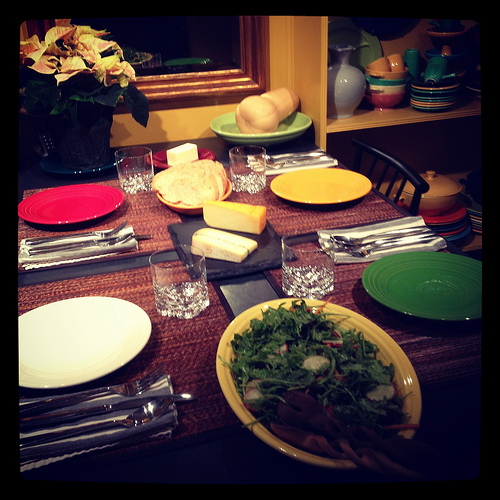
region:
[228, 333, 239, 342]
part of a table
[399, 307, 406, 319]
part of a plate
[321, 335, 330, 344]
part of a vegetable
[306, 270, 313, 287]
part of a glass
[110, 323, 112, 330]
edge of a plate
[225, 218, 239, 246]
part of a cake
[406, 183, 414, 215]
part of a chair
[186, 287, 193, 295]
edge of a glass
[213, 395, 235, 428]
top of a table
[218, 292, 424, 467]
yellow ceramic plate covered with salad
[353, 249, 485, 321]
empty green ceramic plate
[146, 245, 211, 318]
empty fancy drinking glass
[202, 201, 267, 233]
sliced block of muenster cheese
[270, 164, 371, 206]
empty round yellow ceramic plate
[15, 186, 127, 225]
empty round red ceramic plate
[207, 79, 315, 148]
bread rolls on light green plate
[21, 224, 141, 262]
silver utensils on white napkin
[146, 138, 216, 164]
yellow butter stick in red holder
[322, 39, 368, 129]
small grey vase on wooden shelf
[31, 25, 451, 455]
the scene is in a kitchen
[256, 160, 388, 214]
the plate is yellow in colour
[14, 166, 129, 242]
the plate is red in color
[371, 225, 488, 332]
the plate is green in colour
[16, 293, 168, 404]
the plate is white in colour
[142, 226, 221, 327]
the glass is empty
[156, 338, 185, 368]
the table is wooden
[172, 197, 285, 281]
the cheese is in a black plate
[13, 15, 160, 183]
the flowers are in a vase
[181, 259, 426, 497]
the plate is oval in colour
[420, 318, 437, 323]
part of a plate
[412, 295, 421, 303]
edge of a plate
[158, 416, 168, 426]
part of a spoon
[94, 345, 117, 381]
edge of a plate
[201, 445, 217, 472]
part of a cloth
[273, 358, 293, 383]
part of a vegetable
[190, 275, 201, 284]
part of a glass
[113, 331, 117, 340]
part of a plate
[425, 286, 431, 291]
part of a plate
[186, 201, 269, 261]
Cheesecake on the table.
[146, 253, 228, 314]
Empty glass on the table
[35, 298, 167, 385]
White plate on the brown placemat.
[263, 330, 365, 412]
Salad on the bowl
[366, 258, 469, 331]
The plate is green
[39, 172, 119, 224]
The plate is red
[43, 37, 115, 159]
Yellow flowers in the pot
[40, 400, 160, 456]
Silverware next to the plate.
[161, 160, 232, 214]
Bread in the saucer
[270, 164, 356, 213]
A yellow plate on the placemat